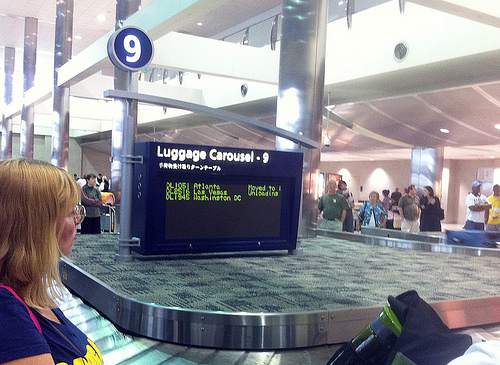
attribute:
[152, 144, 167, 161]
letter — White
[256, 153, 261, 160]
dash symbol — dash 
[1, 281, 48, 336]
strap — red 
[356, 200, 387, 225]
shirt — blue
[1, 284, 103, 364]
shirt — blue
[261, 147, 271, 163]
number — nine , white font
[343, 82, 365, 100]
ground — yellow font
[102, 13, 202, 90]
sign —  blue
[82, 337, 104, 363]
lettering — yellow 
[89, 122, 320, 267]
sign — blue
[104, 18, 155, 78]
sign — number nine 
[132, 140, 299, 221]
sign — blue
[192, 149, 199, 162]
letter — white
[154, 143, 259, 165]
writing — white font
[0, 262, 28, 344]
shoulder — woman's 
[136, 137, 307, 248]
sign — blue 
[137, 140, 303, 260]
sign —  blue, blue, word luggage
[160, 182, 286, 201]
lettering — green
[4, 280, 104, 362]
shirt — blue , blue and yellow, dark blue 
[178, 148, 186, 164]
letter — white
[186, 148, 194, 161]
letter — white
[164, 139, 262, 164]
letter — White 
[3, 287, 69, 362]
shoulder — woman's 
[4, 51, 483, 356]
terminal —  luggage 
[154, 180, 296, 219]
details — written 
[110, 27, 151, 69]
circle — blue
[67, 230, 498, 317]
area — carpeted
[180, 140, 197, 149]
letter — White 